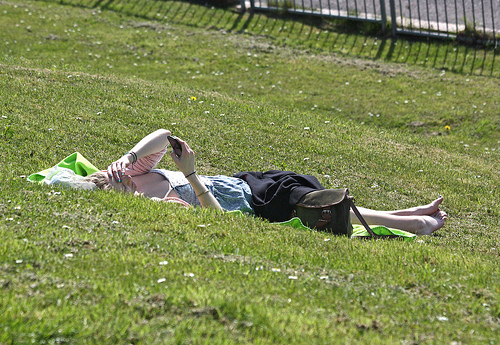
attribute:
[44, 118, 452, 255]
woman — barefoot, lying down, lying on back, blonde haired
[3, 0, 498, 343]
grass — green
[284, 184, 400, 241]
bag — brown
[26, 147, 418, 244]
towel — green, neon green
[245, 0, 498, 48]
fence — black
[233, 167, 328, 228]
jacket — dark colored, black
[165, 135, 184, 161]
cell phone — dark colored, black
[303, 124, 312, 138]
flower — white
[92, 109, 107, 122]
flower — white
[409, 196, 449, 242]
feet — bare, touching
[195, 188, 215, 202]
bracelet — dark colored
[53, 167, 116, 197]
hair — blonde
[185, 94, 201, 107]
flower — yellow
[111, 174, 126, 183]
nai polish — blue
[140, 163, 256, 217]
tank top — light colored